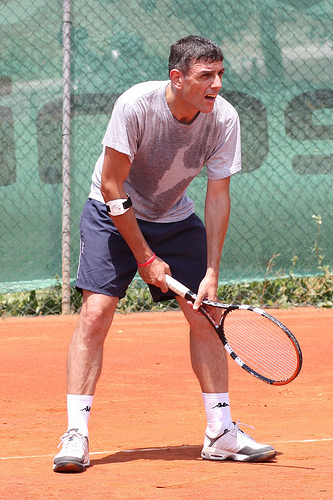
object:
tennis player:
[52, 30, 278, 475]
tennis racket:
[165, 273, 304, 389]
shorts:
[73, 197, 208, 304]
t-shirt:
[86, 79, 243, 226]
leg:
[64, 260, 138, 428]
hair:
[168, 34, 225, 79]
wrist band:
[105, 196, 134, 218]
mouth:
[203, 92, 218, 104]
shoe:
[52, 427, 92, 475]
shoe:
[200, 425, 278, 465]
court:
[0, 306, 333, 500]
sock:
[67, 393, 94, 434]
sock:
[201, 392, 232, 434]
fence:
[1, 0, 331, 308]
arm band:
[136, 253, 156, 268]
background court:
[0, 0, 333, 305]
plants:
[321, 285, 331, 302]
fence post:
[59, 0, 73, 315]